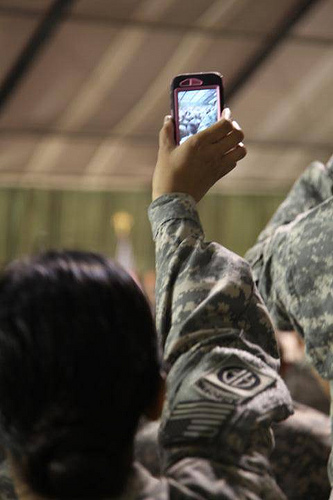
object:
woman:
[0, 107, 294, 499]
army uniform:
[1, 190, 294, 499]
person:
[133, 155, 332, 499]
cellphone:
[170, 72, 223, 147]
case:
[170, 70, 225, 147]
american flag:
[160, 401, 238, 445]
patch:
[192, 352, 278, 406]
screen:
[178, 89, 218, 138]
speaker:
[178, 77, 201, 89]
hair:
[0, 250, 162, 498]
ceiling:
[2, 0, 332, 195]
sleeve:
[148, 192, 294, 499]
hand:
[152, 108, 248, 198]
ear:
[145, 373, 166, 422]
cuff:
[144, 191, 205, 239]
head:
[0, 246, 167, 500]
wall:
[1, 186, 285, 271]